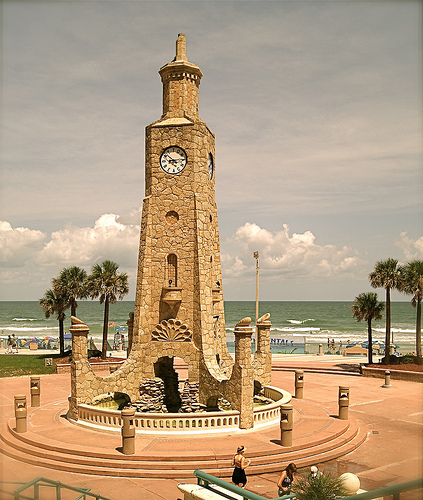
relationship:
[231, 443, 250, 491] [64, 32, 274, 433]
woman beside clock tower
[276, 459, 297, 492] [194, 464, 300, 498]
woman beside metal guardrail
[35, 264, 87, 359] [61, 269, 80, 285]
palm tree covered in leaves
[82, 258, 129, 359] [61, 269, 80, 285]
palm tree covered in leaves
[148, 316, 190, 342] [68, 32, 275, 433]
design on side of clock tower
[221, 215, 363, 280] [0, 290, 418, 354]
cloud above water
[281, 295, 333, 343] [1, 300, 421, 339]
waves in sea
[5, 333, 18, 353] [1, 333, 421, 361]
couple walking donw beach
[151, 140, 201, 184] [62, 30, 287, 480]
clock on tower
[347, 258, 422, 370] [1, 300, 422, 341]
palm trees next to water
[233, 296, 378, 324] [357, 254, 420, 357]
water behind trees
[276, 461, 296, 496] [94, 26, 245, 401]
woman standing in front of tower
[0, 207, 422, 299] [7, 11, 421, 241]
cloud in sky